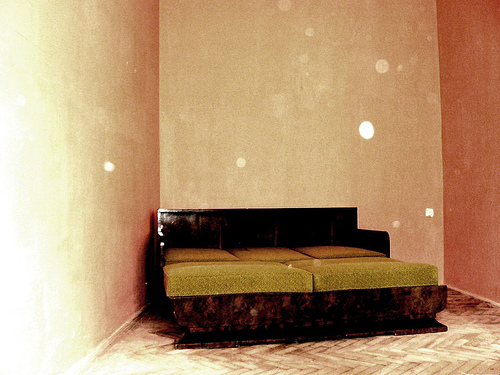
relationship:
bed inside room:
[147, 192, 457, 338] [13, 11, 486, 362]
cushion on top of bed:
[166, 261, 312, 293] [147, 192, 457, 338]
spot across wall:
[374, 57, 392, 76] [187, 13, 257, 77]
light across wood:
[160, 208, 200, 227] [161, 210, 219, 233]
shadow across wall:
[137, 218, 153, 264] [187, 13, 257, 77]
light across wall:
[4, 81, 50, 144] [187, 13, 257, 77]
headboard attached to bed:
[169, 201, 344, 239] [147, 192, 457, 338]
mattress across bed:
[168, 247, 425, 292] [147, 192, 457, 338]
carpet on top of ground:
[172, 321, 459, 345] [422, 342, 476, 371]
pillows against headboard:
[169, 245, 292, 262] [169, 201, 344, 239]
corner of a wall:
[427, 76, 457, 127] [187, 13, 257, 77]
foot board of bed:
[166, 284, 451, 352] [147, 192, 457, 338]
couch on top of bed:
[168, 247, 425, 292] [147, 192, 457, 338]